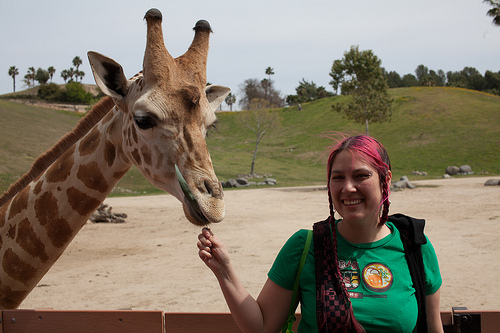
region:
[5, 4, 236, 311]
Head of giraffe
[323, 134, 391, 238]
Pink and brown hair in braids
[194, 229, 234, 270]
Fist near giraffe's head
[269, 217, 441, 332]
Emerald green shirt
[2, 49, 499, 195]
Hill with trees and rocks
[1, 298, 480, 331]
Wooden fence between giraffe and woman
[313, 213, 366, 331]
Red and black checkered bag over woman's shoulder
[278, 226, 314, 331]
Light green strap over right shoulder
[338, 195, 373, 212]
Wide toothy smile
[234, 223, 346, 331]
Shadow between sunny arm and torso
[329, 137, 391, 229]
A woman with pink and brown hair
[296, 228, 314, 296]
The strap of a green bag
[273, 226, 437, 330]
A green t shirt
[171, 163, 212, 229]
A leaf in a giraffe's mouth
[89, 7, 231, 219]
The head of a giraffe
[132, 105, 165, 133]
A giraffe's eye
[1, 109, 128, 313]
The neck of a giraffe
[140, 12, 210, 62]
The short horns of a giraffe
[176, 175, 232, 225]
A giraffe's mouth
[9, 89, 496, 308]
A giraffe enclosure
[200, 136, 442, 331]
girl with pink hair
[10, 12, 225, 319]
a giraffe on the left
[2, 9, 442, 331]
woman feeding the giraffe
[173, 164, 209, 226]
green leaf in giraffe's mouth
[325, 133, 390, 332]
pink hair in braids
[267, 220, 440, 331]
the woman's green t-shirt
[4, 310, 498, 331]
wooden railing between woman and giraffe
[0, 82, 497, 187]
green grassy hills behind giraffe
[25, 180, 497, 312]
dirt area of giraffe pen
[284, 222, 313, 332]
the woman's green purse strap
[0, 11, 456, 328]
woman feeding a giraffe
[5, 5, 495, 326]
woman with pink hair feeding a giraffe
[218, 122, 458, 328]
woman with pink hair wearing a green shirt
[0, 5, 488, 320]
woman with pink and black hair feeding a giraffe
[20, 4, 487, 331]
woman in a green shirt feeding a giraffe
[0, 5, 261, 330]
giraffe grazing on a plant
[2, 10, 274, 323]
giraffe eating a plant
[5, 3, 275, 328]
giraffe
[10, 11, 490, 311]
smiling woman feeding giraffe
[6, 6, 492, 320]
smiling woman standing next to a giraffe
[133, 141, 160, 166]
Brown sopt on a giraffe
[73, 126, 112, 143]
Brown sopt on a giraffe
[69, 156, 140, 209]
Brown sopt on a giraffe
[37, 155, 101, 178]
Brown sopt on a giraffe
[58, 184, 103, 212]
Brown sopt on a giraffe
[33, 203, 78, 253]
Brown sopt on a giraffe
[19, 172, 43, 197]
Brown sopt on a giraffe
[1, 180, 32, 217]
Brown sopt on a giraffe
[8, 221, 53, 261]
Brown sopt on a giraffe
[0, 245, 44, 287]
Brown sopt on a giraffe